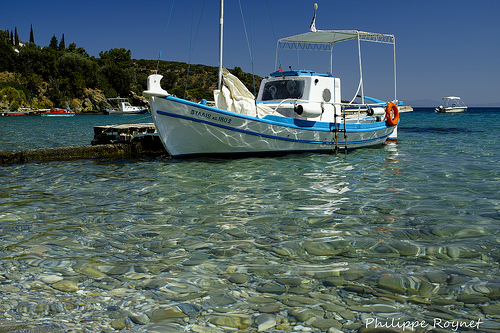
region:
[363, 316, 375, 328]
white colored print letter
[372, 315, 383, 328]
white colored print letter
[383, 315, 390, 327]
white colored print letter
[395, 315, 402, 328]
white colored print letter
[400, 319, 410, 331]
white colored print letter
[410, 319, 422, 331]
white colored print letter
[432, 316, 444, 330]
white colored print letter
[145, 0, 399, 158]
white and blue sailboat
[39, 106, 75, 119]
red and white boat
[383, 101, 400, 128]
orange life saver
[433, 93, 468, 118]
white boat on the lake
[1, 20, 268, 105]
hill with shrubs and pine trees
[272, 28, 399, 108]
canopy attached to a boat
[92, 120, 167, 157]
wood deck next to boat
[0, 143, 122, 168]
metal covered in moss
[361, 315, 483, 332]
The person who took the picture.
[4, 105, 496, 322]
The clear water with rocks.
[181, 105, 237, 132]
The name of the boat.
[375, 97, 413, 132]
The life preserver on the boat.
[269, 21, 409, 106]
The canopy on the boat.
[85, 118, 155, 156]
The small wooden dock near the boat.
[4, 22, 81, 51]
The trees in the background.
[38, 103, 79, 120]
The red boat in the background.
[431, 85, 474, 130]
The white boat in the background.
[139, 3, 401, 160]
white boat with blue trim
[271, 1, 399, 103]
white canopy on rear of boat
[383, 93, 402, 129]
orange life preserver on side of boat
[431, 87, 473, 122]
white boat sailing in distance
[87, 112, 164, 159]
floating dock next to blue and white boat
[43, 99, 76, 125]
red and white ski boat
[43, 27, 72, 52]
trees on top of hill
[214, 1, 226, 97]
metal mast on blue and white boat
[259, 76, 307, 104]
dark glass windshield for boat cabin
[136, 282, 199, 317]
rocks in the water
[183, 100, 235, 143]
words on a boat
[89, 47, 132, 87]
trees on a hill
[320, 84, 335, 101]
window on a boat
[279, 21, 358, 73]
a canopy on a boat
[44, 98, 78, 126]
a red boat in the water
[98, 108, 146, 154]
a pier next to the boat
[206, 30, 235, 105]
a pole on the boat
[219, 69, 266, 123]
a tarp on the boat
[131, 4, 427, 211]
this is a boat